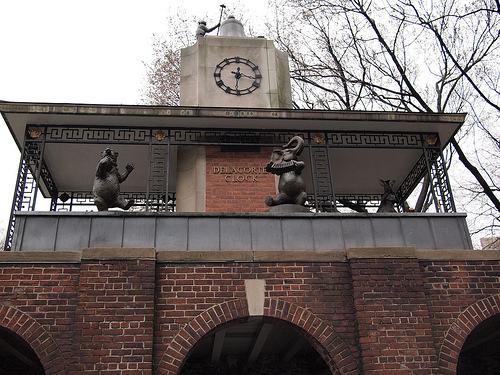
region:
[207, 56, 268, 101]
a clock on a clock tower.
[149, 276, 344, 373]
a brick archway on a building.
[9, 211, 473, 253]
a wall on a building.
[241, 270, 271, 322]
a capstone on an arch.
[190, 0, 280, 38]
a statue on top of a building.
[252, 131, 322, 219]
a statue on a second floor.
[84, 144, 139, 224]
a bear statue on a second floor.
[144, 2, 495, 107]
a tree with no leaves.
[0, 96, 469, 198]
a roof on a building.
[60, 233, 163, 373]
a column of support on a brick building.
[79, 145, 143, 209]
dark bronze statue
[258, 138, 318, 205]
bronze statue of an elephant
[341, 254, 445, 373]
old brick wall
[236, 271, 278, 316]
strip on the wall that doesn't have brick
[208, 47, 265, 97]
clock on the top of the building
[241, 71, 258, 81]
pointed black clock hand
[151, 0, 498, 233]
tree with no leaves on it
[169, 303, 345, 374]
rounded top entrance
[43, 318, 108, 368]
dark spots on the red brick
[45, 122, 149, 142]
black design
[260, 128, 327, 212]
small statue of an elephant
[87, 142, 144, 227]
small statue of a bear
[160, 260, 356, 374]
brick archway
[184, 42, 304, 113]
round clock at 3:30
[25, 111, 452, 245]
small statues on clock tower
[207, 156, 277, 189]
sign fro Delacorte Clock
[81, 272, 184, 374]
section of red brick building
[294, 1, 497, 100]
trees without leaves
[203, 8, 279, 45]
bell on top of clock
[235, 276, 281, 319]
white keystone in an arch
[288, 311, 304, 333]
the arch is bricks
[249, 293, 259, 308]
the arch is bricks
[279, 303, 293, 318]
the arch is bricks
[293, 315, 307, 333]
the arch is bricks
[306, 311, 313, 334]
the arch is bricks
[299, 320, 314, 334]
the arch is bricks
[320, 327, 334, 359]
the arch is bricks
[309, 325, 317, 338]
the arch is bricks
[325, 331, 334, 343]
the arch is bricks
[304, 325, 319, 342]
the arch is bricks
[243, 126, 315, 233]
elephant statue above arch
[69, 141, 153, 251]
dancing bear above arch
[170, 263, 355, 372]
archway made of red brick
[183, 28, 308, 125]
clock above walkway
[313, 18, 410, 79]
dead tree near walkway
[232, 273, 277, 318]
keystone in archway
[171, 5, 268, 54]
monkey ringing bell statue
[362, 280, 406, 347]
red brick making up archway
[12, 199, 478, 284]
metal wall above brick arch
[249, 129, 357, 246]
elephant playing music satute